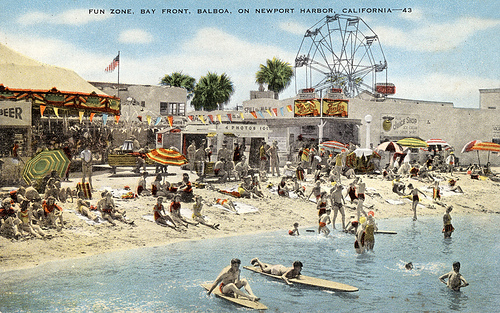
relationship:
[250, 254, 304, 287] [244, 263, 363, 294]
man laying on a surfboard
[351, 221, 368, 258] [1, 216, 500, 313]
woman standing in water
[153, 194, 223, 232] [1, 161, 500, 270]
women are sitting on beach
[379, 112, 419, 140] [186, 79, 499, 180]
sign in front of building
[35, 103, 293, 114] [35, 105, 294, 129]
string supporting flags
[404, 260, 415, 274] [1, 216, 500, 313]
head above water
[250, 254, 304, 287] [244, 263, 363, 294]
man on a surfboard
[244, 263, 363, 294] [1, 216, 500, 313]
surfboard in water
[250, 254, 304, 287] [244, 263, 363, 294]
man on surfboard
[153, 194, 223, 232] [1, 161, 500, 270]
women are on beach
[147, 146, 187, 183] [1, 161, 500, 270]
umbrella on beach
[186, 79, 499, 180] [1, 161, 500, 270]
building behind beach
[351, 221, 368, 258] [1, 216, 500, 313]
woman in water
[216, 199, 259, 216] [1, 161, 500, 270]
towel on beach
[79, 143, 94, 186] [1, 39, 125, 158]
person standing by merry-go-round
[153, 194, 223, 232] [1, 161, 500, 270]
women are at beach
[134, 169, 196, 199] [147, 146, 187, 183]
people are using an umbrella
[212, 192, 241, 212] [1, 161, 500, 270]
person laying on beach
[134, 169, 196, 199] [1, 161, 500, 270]
people are on beach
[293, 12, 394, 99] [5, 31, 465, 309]
ferris wheel in park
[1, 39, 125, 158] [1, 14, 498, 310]
merry-go-round in park